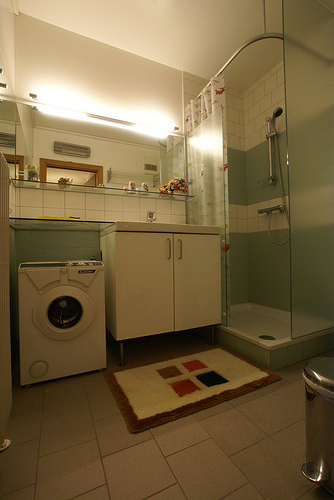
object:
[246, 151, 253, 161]
green tile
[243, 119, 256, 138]
white tile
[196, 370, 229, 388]
square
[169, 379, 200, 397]
square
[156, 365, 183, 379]
square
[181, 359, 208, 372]
square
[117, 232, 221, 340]
doors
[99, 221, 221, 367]
cabinet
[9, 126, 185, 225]
wall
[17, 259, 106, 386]
appliance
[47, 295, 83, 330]
window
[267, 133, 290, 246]
hose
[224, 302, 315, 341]
sink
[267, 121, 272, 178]
pipe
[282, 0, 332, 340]
glass door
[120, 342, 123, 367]
leg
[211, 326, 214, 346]
leg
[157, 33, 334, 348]
shower stall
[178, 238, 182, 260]
handle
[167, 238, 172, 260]
handle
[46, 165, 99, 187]
mirror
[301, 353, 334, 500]
metal can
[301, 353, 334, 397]
lid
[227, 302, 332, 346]
floor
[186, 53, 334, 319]
wall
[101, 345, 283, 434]
bathmat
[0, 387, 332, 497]
floor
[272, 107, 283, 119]
shower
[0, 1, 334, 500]
bathroom